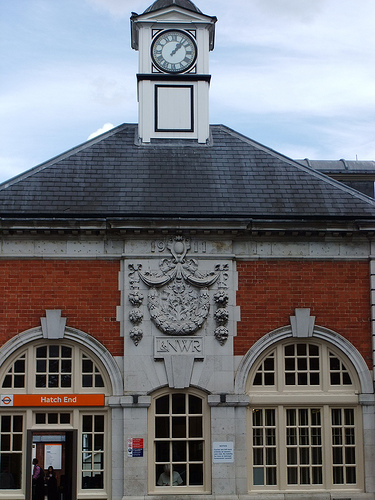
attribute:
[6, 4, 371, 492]
building — red, brick, old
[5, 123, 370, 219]
roof — tile, black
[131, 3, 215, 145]
tower — white, trimmed in black, trimmed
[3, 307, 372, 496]
windows — arched, trimmed, in stone, glass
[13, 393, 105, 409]
sign — orange, white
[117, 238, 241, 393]
sculpture — stone, concrete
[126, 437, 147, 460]
sign — red, black, white, on the side, blue, to the right, right of entryway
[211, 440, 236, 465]
sign — white, on the side, to the right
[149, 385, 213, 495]
window — in the center, small, in middle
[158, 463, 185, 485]
person — sitting, in center, old, standing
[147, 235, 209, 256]
1911 — year, on side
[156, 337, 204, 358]
sign — nwr, old, cement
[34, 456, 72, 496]
people — in a group, standing, sheltered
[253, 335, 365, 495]
window — large, on the right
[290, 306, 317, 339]
stone — decorative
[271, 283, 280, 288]
brick — red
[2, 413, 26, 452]
window — smaller